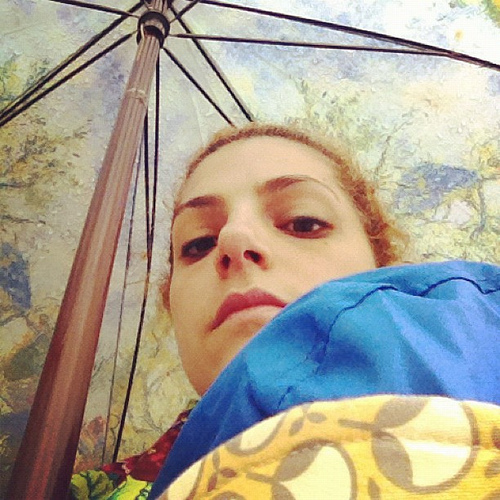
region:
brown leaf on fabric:
[358, 423, 403, 490]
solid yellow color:
[309, 473, 338, 493]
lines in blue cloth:
[302, 302, 428, 352]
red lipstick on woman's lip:
[208, 269, 295, 317]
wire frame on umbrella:
[111, 296, 153, 463]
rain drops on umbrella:
[24, 167, 86, 253]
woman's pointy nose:
[199, 212, 283, 279]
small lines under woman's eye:
[271, 221, 353, 260]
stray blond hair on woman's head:
[343, 138, 408, 230]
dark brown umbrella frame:
[41, 157, 122, 479]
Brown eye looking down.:
[275, 200, 345, 245]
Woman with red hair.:
[148, 130, 425, 386]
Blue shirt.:
[298, 290, 498, 418]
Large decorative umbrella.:
[3, 3, 495, 125]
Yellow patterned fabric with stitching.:
[208, 422, 488, 492]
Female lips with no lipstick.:
[202, 280, 285, 336]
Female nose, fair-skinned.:
[212, 205, 272, 280]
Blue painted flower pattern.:
[385, 143, 485, 223]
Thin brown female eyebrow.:
[247, 165, 355, 210]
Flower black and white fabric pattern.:
[342, 397, 489, 497]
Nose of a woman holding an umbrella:
[212, 209, 273, 269]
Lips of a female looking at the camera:
[202, 283, 292, 334]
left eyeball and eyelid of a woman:
[273, 211, 334, 236]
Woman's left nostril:
[238, 251, 261, 261]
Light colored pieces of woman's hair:
[353, 165, 407, 269]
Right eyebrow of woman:
[171, 188, 223, 214]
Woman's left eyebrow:
[257, 171, 339, 199]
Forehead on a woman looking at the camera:
[181, 133, 324, 200]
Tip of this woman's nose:
[212, 226, 261, 251]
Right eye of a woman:
[179, 235, 216, 256]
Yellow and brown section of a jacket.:
[154, 389, 499, 498]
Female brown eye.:
[275, 213, 335, 239]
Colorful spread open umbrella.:
[4, 0, 498, 485]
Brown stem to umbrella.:
[1, 0, 181, 497]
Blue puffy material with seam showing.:
[152, 247, 495, 498]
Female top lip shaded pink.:
[206, 280, 291, 339]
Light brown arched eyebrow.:
[251, 170, 348, 206]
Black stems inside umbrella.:
[168, 1, 498, 99]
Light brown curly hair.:
[335, 146, 419, 264]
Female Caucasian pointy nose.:
[215, 204, 271, 280]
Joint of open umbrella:
[96, 5, 208, 43]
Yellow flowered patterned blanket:
[263, 422, 425, 494]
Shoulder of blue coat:
[309, 295, 452, 370]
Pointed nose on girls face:
[203, 220, 279, 267]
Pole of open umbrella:
[34, 123, 119, 449]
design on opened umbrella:
[391, 91, 494, 220]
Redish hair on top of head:
[265, 122, 392, 144]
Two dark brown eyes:
[162, 208, 337, 261]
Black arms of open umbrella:
[12, 83, 89, 118]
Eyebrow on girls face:
[251, 171, 343, 196]